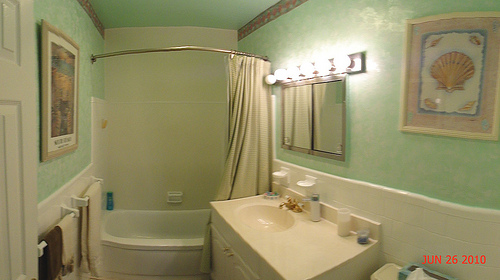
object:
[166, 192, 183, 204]
dish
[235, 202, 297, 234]
sink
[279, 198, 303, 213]
facet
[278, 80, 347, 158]
reflection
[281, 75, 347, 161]
mirror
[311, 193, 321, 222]
bottle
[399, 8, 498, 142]
picture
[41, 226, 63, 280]
bowl towel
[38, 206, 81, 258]
bar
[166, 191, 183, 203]
holder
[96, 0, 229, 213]
wall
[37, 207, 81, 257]
rod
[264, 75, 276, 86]
light bulb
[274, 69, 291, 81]
light bulb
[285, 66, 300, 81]
light bulb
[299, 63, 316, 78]
light bulb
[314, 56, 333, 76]
light bulb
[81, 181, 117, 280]
towel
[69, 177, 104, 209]
rod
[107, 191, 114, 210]
blue bottle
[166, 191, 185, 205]
soap dish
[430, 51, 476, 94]
sea shell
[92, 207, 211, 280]
tub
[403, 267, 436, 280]
tissue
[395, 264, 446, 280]
box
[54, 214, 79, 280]
towel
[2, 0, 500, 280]
bathroom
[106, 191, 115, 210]
shampoo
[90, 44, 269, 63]
rod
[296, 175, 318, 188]
soap dish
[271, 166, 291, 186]
soap dish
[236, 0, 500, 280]
wall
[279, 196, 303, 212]
faucet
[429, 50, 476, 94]
shell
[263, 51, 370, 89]
row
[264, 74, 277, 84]
light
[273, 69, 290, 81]
light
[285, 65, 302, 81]
light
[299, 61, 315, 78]
light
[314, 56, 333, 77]
light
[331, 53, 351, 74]
light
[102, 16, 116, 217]
corner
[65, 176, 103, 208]
holder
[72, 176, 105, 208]
bar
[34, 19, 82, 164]
picture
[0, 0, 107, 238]
wall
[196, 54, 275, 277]
curtain